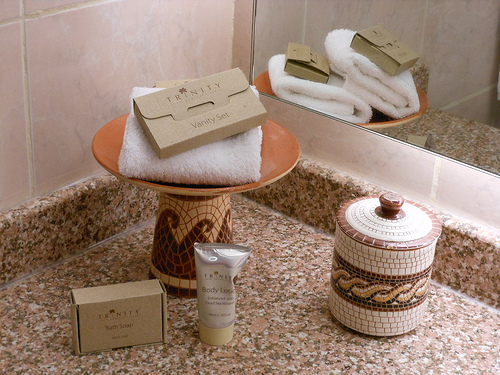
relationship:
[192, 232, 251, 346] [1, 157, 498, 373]
tube on counter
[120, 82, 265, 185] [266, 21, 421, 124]
towel has reflection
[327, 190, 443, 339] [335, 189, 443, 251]
container has cover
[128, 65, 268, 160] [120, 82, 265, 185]
box over towel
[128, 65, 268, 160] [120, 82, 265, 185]
box on towel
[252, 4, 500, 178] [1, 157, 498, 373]
mirror above counter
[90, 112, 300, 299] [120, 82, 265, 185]
stand has towel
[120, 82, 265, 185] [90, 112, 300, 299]
towel on top of stand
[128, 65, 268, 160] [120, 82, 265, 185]
box on top of towel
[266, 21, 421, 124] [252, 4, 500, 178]
reflection in mirror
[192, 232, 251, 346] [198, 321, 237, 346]
tube has cap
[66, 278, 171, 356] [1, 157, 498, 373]
box on counter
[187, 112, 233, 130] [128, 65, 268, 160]
vanity set written on box